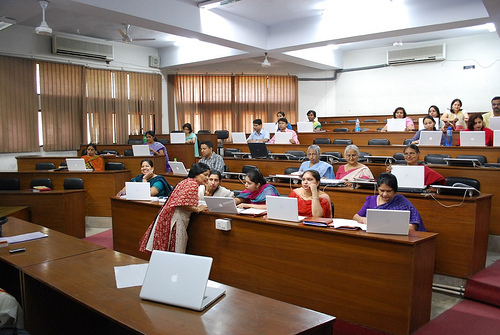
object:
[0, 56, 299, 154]
curtains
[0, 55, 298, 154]
window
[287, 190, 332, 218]
shirt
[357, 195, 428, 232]
shirt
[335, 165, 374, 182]
shirt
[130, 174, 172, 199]
shirt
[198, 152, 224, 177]
shirt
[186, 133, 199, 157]
shirt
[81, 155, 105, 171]
shirt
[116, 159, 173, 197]
woman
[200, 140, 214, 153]
hair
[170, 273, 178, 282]
logo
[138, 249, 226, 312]
laptop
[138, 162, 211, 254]
people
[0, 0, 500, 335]
classroom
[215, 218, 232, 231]
outlet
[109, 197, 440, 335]
desk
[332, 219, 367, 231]
paper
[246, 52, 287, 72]
fans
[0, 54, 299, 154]
shades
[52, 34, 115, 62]
conditioner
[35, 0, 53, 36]
light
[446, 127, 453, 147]
bottle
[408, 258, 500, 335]
rug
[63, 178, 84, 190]
chair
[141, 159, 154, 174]
head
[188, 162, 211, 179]
hair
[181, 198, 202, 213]
arm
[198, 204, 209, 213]
hand